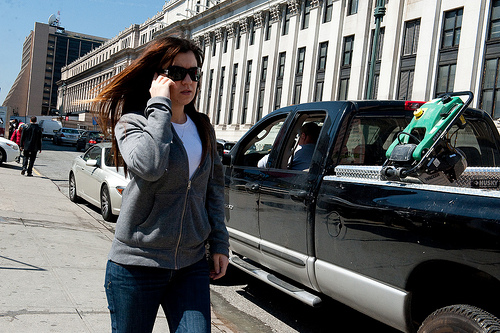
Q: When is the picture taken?
A: Daytime.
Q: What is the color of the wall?
A: Grey.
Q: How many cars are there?
A: 4.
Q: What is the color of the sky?
A: Blue.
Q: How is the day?
A: Sunny.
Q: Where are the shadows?
A: In the road.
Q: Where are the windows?
A: In the building wall.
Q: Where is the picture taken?
A: Walking down the street.